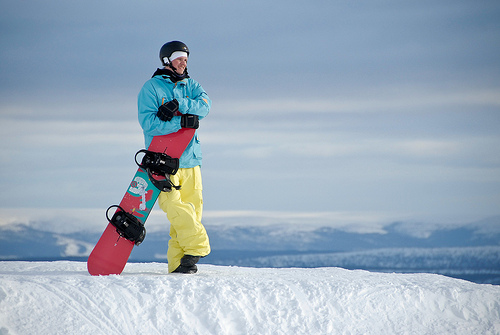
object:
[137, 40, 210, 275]
man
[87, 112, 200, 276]
board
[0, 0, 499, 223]
sky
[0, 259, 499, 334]
snow